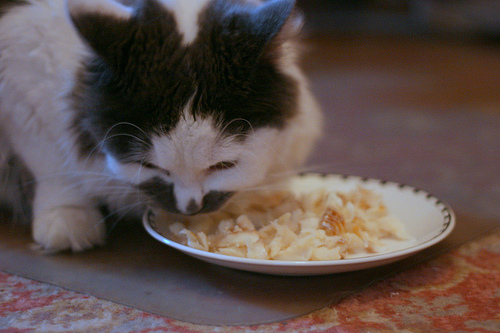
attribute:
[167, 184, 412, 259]
cat food — white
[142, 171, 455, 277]
plate — white, round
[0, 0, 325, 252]
cat — white, black, grey, eating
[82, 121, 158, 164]
whisker — white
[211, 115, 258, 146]
whisker — white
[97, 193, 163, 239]
whisker — white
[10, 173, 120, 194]
whisker — white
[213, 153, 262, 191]
whisker — white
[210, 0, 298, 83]
ear — grey, black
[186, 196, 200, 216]
dot — black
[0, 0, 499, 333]
carpet — red, orange, brown, printed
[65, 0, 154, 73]
ear — black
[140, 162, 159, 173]
eye — black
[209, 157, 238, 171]
eye — black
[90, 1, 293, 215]
cat face — black, white